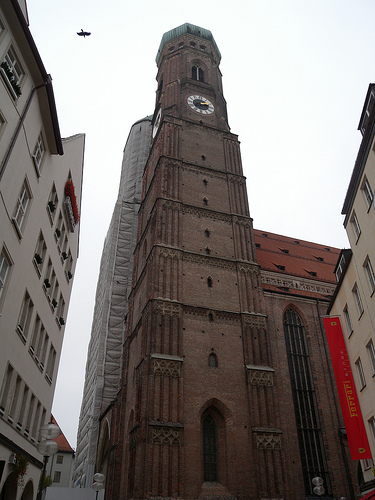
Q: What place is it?
A: It is a church.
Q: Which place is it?
A: It is a church.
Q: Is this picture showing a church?
A: Yes, it is showing a church.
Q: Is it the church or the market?
A: It is the church.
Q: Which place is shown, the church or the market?
A: It is the church.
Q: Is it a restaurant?
A: No, it is a church.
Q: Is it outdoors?
A: Yes, it is outdoors.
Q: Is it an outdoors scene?
A: Yes, it is outdoors.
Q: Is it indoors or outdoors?
A: It is outdoors.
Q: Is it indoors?
A: No, it is outdoors.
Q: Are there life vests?
A: No, there are no life vests.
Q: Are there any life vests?
A: No, there are no life vests.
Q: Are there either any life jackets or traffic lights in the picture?
A: No, there are no life jackets or traffic lights.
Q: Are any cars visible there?
A: No, there are no cars.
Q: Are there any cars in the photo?
A: No, there are no cars.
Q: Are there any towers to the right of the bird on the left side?
A: Yes, there is a tower to the right of the bird.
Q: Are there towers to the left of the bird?
A: No, the tower is to the right of the bird.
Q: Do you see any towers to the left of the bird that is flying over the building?
A: No, the tower is to the right of the bird.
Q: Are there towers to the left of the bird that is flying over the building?
A: No, the tower is to the right of the bird.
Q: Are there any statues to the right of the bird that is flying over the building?
A: No, there is a tower to the right of the bird.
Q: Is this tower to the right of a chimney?
A: No, the tower is to the right of the bird.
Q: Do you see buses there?
A: No, there are no buses.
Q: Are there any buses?
A: No, there are no buses.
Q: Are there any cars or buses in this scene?
A: No, there are no buses or cars.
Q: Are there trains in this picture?
A: No, there are no trains.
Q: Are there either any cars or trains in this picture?
A: No, there are no trains or cars.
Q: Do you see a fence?
A: Yes, there is a fence.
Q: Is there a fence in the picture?
A: Yes, there is a fence.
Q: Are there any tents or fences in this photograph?
A: Yes, there is a fence.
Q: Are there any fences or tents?
A: Yes, there is a fence.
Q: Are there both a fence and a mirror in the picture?
A: No, there is a fence but no mirrors.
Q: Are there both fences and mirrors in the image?
A: No, there is a fence but no mirrors.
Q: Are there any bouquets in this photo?
A: No, there are no bouquets.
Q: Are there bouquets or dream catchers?
A: No, there are no bouquets or dream catchers.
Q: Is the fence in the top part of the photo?
A: Yes, the fence is in the top of the image.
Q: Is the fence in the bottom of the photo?
A: No, the fence is in the top of the image.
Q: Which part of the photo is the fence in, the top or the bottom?
A: The fence is in the top of the image.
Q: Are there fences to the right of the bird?
A: Yes, there is a fence to the right of the bird.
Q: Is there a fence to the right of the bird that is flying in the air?
A: Yes, there is a fence to the right of the bird.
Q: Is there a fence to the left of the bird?
A: No, the fence is to the right of the bird.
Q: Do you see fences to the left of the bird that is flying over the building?
A: No, the fence is to the right of the bird.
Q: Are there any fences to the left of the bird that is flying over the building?
A: No, the fence is to the right of the bird.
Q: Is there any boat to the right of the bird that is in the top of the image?
A: No, there is a fence to the right of the bird.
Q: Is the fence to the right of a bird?
A: Yes, the fence is to the right of a bird.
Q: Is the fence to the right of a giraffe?
A: No, the fence is to the right of a bird.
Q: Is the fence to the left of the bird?
A: No, the fence is to the right of the bird.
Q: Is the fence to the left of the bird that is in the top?
A: No, the fence is to the right of the bird.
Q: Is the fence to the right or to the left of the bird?
A: The fence is to the right of the bird.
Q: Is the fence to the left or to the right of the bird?
A: The fence is to the right of the bird.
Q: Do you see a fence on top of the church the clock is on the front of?
A: Yes, there is a fence on top of the church.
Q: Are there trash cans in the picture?
A: No, there are no trash cans.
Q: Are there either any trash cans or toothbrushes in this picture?
A: No, there are no trash cans or toothbrushes.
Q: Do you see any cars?
A: No, there are no cars.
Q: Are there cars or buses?
A: No, there are no cars or buses.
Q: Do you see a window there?
A: Yes, there is a window.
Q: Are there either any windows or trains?
A: Yes, there is a window.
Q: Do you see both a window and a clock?
A: Yes, there are both a window and a clock.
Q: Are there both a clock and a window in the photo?
A: Yes, there are both a window and a clock.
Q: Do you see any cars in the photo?
A: No, there are no cars.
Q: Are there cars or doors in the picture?
A: No, there are no cars or doors.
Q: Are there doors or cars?
A: No, there are no cars or doors.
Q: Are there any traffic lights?
A: No, there are no traffic lights.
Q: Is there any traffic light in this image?
A: No, there are no traffic lights.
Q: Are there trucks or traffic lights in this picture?
A: No, there are no traffic lights or trucks.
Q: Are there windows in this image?
A: Yes, there is a window.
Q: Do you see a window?
A: Yes, there is a window.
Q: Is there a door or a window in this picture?
A: Yes, there is a window.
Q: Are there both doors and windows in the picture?
A: No, there is a window but no doors.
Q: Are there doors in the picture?
A: No, there are no doors.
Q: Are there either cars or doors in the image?
A: No, there are no doors or cars.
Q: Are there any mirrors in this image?
A: No, there are no mirrors.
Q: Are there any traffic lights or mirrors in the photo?
A: No, there are no mirrors or traffic lights.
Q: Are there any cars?
A: No, there are no cars.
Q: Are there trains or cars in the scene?
A: No, there are no cars or trains.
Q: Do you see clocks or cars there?
A: Yes, there is a clock.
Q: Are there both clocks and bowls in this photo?
A: No, there is a clock but no bowls.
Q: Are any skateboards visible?
A: No, there are no skateboards.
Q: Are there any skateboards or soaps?
A: No, there are no skateboards or soaps.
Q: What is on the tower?
A: The clock is on the tower.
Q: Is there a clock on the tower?
A: Yes, there is a clock on the tower.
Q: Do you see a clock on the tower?
A: Yes, there is a clock on the tower.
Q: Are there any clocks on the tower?
A: Yes, there is a clock on the tower.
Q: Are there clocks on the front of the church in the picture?
A: Yes, there is a clock on the front of the church.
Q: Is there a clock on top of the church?
A: Yes, there is a clock on top of the church.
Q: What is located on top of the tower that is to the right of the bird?
A: The clock is on top of the tower.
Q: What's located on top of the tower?
A: The clock is on top of the tower.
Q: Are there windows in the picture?
A: Yes, there is a window.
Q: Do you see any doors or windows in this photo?
A: Yes, there is a window.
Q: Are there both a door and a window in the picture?
A: No, there is a window but no doors.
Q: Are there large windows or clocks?
A: Yes, there is a large window.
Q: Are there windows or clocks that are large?
A: Yes, the window is large.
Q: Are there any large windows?
A: Yes, there is a large window.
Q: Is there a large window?
A: Yes, there is a large window.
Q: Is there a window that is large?
A: Yes, there is a window that is large.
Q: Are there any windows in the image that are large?
A: Yes, there is a window that is large.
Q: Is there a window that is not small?
A: Yes, there is a large window.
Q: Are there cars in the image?
A: No, there are no cars.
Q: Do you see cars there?
A: No, there are no cars.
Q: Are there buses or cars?
A: No, there are no cars or buses.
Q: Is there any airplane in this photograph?
A: No, there are no airplanes.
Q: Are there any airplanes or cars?
A: No, there are no airplanes or cars.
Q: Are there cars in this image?
A: No, there are no cars.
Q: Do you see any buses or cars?
A: No, there are no cars or buses.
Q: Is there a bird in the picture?
A: Yes, there is a bird.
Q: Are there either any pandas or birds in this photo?
A: Yes, there is a bird.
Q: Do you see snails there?
A: No, there are no snails.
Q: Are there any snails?
A: No, there are no snails.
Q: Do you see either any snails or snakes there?
A: No, there are no snails or snakes.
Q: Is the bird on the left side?
A: Yes, the bird is on the left of the image.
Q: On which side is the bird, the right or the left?
A: The bird is on the left of the image.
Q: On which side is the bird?
A: The bird is on the left of the image.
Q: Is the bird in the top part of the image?
A: Yes, the bird is in the top of the image.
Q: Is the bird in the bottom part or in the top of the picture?
A: The bird is in the top of the image.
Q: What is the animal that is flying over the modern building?
A: The animal is a bird.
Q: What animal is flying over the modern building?
A: The animal is a bird.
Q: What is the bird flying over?
A: The bird is flying over the building.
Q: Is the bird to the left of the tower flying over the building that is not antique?
A: Yes, the bird is flying over the building.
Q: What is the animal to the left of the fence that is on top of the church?
A: The animal is a bird.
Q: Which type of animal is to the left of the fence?
A: The animal is a bird.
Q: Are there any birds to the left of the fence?
A: Yes, there is a bird to the left of the fence.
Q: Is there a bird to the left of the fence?
A: Yes, there is a bird to the left of the fence.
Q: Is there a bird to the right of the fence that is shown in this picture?
A: No, the bird is to the left of the fence.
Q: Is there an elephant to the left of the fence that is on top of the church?
A: No, there is a bird to the left of the fence.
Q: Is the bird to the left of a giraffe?
A: No, the bird is to the left of the fence.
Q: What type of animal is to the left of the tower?
A: The animal is a bird.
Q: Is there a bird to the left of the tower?
A: Yes, there is a bird to the left of the tower.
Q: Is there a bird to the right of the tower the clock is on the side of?
A: No, the bird is to the left of the tower.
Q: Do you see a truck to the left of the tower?
A: No, there is a bird to the left of the tower.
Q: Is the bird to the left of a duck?
A: No, the bird is to the left of the tower.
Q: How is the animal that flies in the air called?
A: The animal is a bird.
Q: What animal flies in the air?
A: The animal is a bird.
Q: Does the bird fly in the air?
A: Yes, the bird flies in the air.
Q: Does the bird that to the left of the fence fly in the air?
A: Yes, the bird flies in the air.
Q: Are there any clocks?
A: Yes, there is a clock.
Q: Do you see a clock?
A: Yes, there is a clock.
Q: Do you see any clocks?
A: Yes, there is a clock.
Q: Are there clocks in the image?
A: Yes, there is a clock.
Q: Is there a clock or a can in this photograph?
A: Yes, there is a clock.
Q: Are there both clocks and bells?
A: No, there is a clock but no bells.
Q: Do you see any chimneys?
A: No, there are no chimneys.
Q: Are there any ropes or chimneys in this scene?
A: No, there are no chimneys or ropes.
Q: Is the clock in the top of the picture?
A: Yes, the clock is in the top of the image.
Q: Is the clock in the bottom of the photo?
A: No, the clock is in the top of the image.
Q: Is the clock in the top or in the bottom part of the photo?
A: The clock is in the top of the image.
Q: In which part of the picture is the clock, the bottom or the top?
A: The clock is in the top of the image.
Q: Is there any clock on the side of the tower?
A: Yes, there is a clock on the side of the tower.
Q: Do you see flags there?
A: Yes, there is a flag.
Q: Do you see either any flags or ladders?
A: Yes, there is a flag.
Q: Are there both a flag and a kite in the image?
A: No, there is a flag but no kites.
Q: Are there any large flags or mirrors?
A: Yes, there is a large flag.